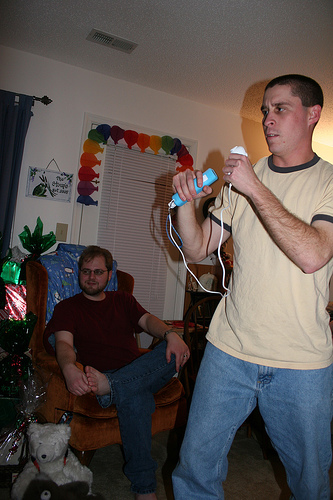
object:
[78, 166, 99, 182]
balloon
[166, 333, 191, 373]
hand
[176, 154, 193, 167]
balloon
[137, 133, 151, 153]
balloon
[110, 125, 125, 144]
balloon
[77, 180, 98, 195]
balloon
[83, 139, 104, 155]
balloon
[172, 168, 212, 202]
hand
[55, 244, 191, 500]
man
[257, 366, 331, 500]
legs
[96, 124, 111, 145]
paper balloon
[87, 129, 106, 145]
paper balloon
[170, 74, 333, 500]
man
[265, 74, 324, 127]
hair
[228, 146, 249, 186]
controller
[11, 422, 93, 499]
bear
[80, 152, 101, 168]
balloon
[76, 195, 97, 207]
balloon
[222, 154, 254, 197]
hand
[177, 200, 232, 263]
arm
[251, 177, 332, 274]
arm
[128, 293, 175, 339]
arm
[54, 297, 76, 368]
arm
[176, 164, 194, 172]
paper balloon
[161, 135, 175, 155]
paper balloon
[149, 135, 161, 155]
paper balloon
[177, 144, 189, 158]
paper balloon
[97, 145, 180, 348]
window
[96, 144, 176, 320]
blinds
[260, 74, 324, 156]
head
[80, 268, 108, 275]
glasses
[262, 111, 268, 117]
eye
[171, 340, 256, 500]
leg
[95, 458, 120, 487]
floor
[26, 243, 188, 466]
chair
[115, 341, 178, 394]
leg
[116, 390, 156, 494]
leg